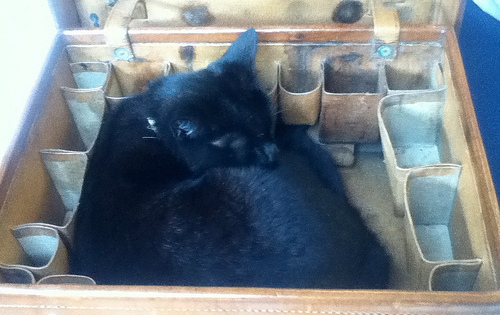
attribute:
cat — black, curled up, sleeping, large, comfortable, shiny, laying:
[70, 23, 399, 290]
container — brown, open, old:
[4, 30, 499, 314]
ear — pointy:
[210, 26, 261, 90]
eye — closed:
[207, 131, 251, 152]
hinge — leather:
[99, 0, 140, 68]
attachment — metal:
[110, 45, 134, 64]